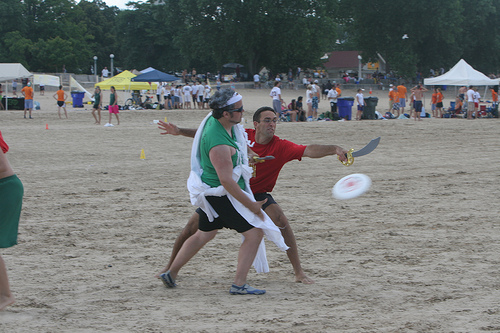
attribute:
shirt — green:
[199, 115, 247, 193]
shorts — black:
[196, 193, 255, 232]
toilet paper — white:
[187, 111, 290, 251]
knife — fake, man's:
[343, 136, 383, 168]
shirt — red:
[245, 126, 308, 194]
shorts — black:
[252, 190, 277, 210]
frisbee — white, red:
[329, 172, 371, 202]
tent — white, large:
[422, 57, 498, 101]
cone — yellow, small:
[135, 146, 147, 162]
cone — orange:
[42, 121, 50, 132]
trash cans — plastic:
[334, 94, 378, 123]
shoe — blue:
[227, 282, 268, 297]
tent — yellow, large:
[94, 70, 158, 92]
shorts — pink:
[106, 103, 121, 116]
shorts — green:
[2, 174, 25, 250]